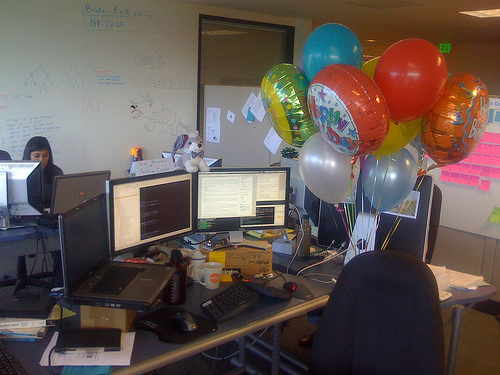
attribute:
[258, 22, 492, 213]
balloons — multiple, bouquet, lot, helium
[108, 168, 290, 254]
monitors — black, wide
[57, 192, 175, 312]
laptop — powerless, black, open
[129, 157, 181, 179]
card — signed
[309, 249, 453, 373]
chair — black, gray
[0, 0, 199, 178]
board — white, dry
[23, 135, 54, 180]
hair — brown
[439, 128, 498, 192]
notes — sticky, pink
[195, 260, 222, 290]
mug — orange, white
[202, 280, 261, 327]
keyboard — black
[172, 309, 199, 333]
mouse — black, silver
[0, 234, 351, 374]
desk — white, gray, grey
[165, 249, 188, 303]
bottle — water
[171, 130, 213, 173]
animal — small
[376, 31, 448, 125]
balloon — mylar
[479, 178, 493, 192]
note — stuck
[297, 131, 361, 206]
balloon — white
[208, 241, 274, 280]
box — small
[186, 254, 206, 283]
cup — white